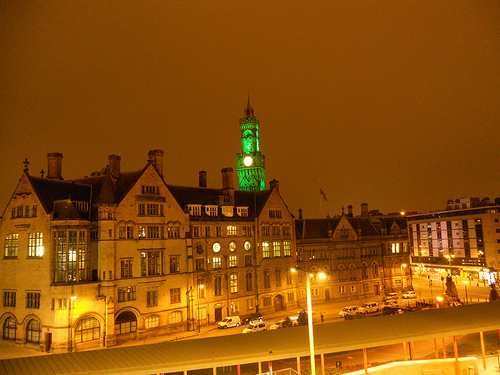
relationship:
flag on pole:
[315, 188, 339, 203] [316, 185, 329, 218]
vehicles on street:
[336, 304, 360, 318] [165, 268, 426, 345]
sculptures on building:
[18, 151, 55, 181] [35, 140, 493, 370]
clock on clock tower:
[243, 154, 256, 167] [235, 103, 270, 203]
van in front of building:
[219, 313, 235, 330] [35, 140, 493, 370]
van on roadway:
[219, 313, 235, 330] [131, 278, 397, 360]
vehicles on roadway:
[194, 288, 400, 341] [131, 278, 397, 360]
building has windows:
[35, 140, 493, 370] [223, 236, 304, 276]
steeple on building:
[235, 108, 266, 158] [35, 140, 493, 370]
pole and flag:
[316, 185, 329, 218] [315, 188, 339, 203]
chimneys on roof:
[39, 143, 233, 185] [7, 167, 309, 209]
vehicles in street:
[336, 304, 360, 318] [165, 268, 426, 345]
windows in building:
[223, 236, 304, 276] [35, 140, 493, 370]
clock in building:
[243, 154, 256, 167] [35, 140, 493, 370]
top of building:
[182, 99, 265, 184] [35, 140, 493, 370]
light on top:
[237, 115, 267, 190] [182, 99, 265, 184]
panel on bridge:
[33, 295, 494, 371] [199, 283, 482, 374]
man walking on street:
[312, 308, 325, 319] [165, 268, 426, 345]